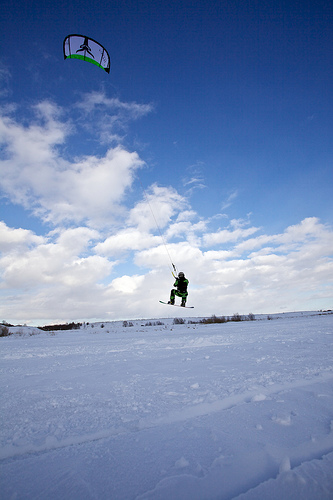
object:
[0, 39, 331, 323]
clouds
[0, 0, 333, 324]
sky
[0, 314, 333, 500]
snow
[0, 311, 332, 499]
ground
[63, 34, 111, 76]
kite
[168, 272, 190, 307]
man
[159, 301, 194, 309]
snowboard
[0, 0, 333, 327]
air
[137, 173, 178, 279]
kite string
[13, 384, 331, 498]
markings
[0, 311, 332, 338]
trees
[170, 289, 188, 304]
pants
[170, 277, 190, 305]
clothes